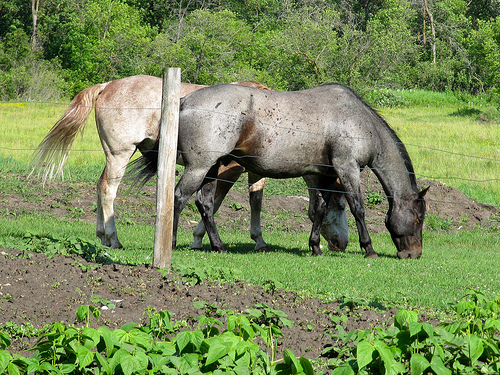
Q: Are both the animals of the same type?
A: Yes, all the animals are horses.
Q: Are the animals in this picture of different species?
A: No, all the animals are horses.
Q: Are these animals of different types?
A: No, all the animals are horses.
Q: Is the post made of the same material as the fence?
A: No, the post is made of wood and the fence is made of metal.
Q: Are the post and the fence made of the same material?
A: No, the post is made of wood and the fence is made of metal.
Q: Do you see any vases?
A: No, there are no vases.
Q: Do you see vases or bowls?
A: No, there are no vases or bowls.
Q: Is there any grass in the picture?
A: Yes, there is grass.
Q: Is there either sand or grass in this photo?
A: Yes, there is grass.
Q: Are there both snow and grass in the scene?
A: No, there is grass but no snow.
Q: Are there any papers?
A: No, there are no papers.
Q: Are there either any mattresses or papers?
A: No, there are no papers or mattresses.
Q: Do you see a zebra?
A: No, there are no zebras.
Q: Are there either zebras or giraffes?
A: No, there are no zebras or giraffes.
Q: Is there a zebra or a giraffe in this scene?
A: No, there are no zebras or giraffes.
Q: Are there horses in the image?
A: Yes, there is a horse.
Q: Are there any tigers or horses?
A: Yes, there is a horse.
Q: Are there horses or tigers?
A: Yes, there is a horse.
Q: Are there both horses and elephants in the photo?
A: No, there is a horse but no elephants.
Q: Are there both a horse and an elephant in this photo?
A: No, there is a horse but no elephants.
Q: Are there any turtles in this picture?
A: No, there are no turtles.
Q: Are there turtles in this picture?
A: No, there are no turtles.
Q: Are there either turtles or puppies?
A: No, there are no turtles or puppies.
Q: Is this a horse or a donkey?
A: This is a horse.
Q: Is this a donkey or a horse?
A: This is a horse.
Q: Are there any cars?
A: No, there are no cars.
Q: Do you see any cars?
A: No, there are no cars.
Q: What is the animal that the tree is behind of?
A: The animal is a horse.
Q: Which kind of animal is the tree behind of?
A: The tree is behind the horse.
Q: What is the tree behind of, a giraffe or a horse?
A: The tree is behind a horse.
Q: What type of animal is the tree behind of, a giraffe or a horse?
A: The tree is behind a horse.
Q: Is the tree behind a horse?
A: Yes, the tree is behind a horse.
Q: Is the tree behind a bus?
A: No, the tree is behind a horse.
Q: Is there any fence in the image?
A: Yes, there is a fence.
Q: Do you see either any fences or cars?
A: Yes, there is a fence.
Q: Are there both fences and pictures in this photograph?
A: No, there is a fence but no pictures.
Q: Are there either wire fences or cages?
A: Yes, there is a wire fence.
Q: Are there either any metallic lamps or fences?
A: Yes, there is a metal fence.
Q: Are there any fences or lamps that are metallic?
A: Yes, the fence is metallic.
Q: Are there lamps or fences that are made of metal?
A: Yes, the fence is made of metal.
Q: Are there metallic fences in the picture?
A: Yes, there is a metal fence.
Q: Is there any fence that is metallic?
A: Yes, there is a fence that is metallic.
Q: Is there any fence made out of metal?
A: Yes, there is a fence that is made of metal.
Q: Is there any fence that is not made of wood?
A: Yes, there is a fence that is made of metal.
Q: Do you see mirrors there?
A: No, there are no mirrors.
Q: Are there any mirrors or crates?
A: No, there are no mirrors or crates.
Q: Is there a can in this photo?
A: No, there are no cans.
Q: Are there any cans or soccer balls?
A: No, there are no cans or soccer balls.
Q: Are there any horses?
A: Yes, there is a horse.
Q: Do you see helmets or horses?
A: Yes, there is a horse.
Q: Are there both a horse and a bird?
A: No, there is a horse but no birds.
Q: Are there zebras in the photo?
A: No, there are no zebras.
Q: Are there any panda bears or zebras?
A: No, there are no zebras or panda bears.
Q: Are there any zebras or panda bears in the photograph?
A: No, there are no zebras or panda bears.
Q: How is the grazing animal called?
A: The animal is a horse.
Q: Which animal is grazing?
A: The animal is a horse.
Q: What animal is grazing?
A: The animal is a horse.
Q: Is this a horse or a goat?
A: This is a horse.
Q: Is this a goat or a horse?
A: This is a horse.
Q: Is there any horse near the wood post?
A: Yes, there is a horse near the post.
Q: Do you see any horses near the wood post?
A: Yes, there is a horse near the post.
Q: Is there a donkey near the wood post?
A: No, there is a horse near the post.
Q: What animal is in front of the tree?
A: The horse is in front of the tree.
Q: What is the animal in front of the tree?
A: The animal is a horse.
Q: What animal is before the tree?
A: The animal is a horse.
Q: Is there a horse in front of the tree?
A: Yes, there is a horse in front of the tree.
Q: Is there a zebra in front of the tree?
A: No, there is a horse in front of the tree.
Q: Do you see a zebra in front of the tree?
A: No, there is a horse in front of the tree.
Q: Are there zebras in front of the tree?
A: No, there is a horse in front of the tree.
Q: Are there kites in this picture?
A: No, there are no kites.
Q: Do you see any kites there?
A: No, there are no kites.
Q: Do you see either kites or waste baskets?
A: No, there are no kites or waste baskets.